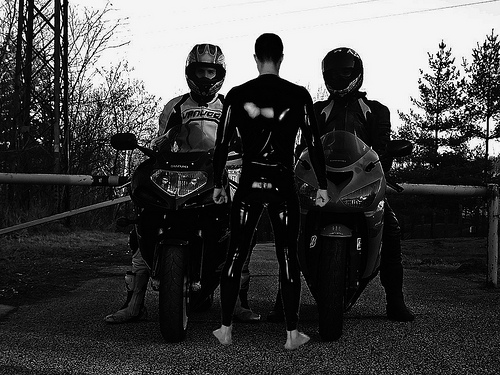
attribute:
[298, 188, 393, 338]
bike — black, rubber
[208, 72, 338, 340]
bodysuit — black, rubber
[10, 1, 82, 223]
electrical pole — grey, metal